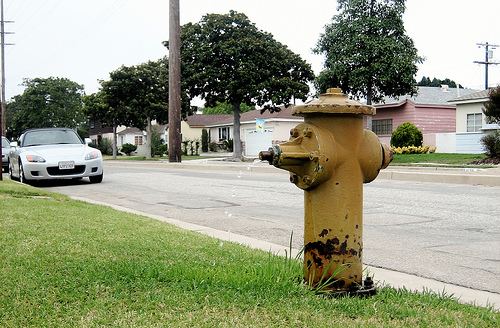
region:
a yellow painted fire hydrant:
[258, 87, 393, 297]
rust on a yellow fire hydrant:
[301, 227, 365, 284]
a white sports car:
[8, 127, 103, 183]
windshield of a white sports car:
[22, 128, 88, 144]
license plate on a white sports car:
[56, 159, 73, 169]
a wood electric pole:
[167, 1, 179, 161]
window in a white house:
[465, 112, 482, 133]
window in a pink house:
[372, 115, 393, 133]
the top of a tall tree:
[313, 1, 423, 88]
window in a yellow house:
[215, 127, 229, 142]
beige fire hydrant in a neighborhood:
[257, 87, 395, 298]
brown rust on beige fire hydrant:
[302, 212, 359, 279]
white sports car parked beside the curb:
[7, 126, 104, 186]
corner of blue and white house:
[447, 85, 481, 153]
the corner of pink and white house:
[372, 86, 432, 150]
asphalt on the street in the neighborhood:
[390, 181, 498, 271]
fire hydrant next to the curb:
[256, 88, 393, 299]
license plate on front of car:
[57, 160, 74, 170]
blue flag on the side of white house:
[254, 117, 265, 133]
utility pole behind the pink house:
[474, 42, 499, 87]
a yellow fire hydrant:
[251, 61, 433, 307]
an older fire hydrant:
[202, 50, 454, 325]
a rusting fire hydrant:
[216, 63, 417, 323]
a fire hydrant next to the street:
[229, 67, 439, 310]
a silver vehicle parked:
[9, 110, 139, 213]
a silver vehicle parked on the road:
[4, 110, 140, 217]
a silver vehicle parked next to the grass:
[17, 96, 138, 212]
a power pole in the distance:
[464, 32, 497, 86]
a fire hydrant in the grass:
[200, 36, 422, 323]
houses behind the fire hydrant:
[168, 89, 365, 192]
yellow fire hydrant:
[269, 77, 406, 308]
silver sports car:
[5, 123, 112, 190]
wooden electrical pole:
[163, 2, 190, 167]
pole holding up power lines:
[470, 32, 497, 97]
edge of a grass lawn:
[0, 167, 260, 327]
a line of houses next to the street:
[95, 62, 497, 185]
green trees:
[11, 0, 432, 132]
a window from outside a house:
[462, 109, 486, 135]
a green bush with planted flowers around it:
[390, 121, 433, 156]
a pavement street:
[117, 158, 499, 303]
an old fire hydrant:
[233, 50, 451, 302]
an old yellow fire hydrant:
[162, 40, 435, 306]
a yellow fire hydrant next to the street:
[230, 59, 450, 295]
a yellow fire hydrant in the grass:
[246, 50, 456, 310]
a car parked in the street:
[10, 100, 143, 217]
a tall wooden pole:
[148, 10, 222, 196]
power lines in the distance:
[432, 32, 497, 82]